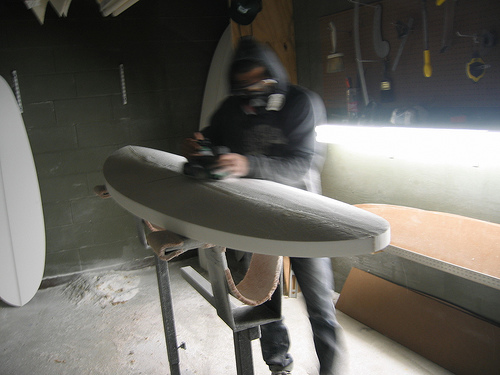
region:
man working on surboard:
[91, 47, 364, 373]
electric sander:
[185, 135, 228, 183]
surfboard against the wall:
[4, 75, 46, 318]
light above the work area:
[319, 118, 499, 173]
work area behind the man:
[317, 201, 499, 346]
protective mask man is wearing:
[232, 79, 289, 123]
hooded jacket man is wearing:
[211, 48, 313, 185]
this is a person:
[172, 32, 367, 368]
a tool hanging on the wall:
[370, 27, 406, 107]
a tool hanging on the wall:
[328, 10, 374, 118]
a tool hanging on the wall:
[398, 5, 453, 110]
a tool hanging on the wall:
[456, 11, 496, 101]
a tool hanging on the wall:
[102, 30, 147, 125]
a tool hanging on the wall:
[5, 61, 35, 127]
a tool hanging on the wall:
[312, 10, 353, 106]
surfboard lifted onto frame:
[103, 144, 391, 368]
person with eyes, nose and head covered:
[220, 30, 295, 118]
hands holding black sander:
[174, 132, 256, 185]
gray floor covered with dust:
[4, 249, 429, 369]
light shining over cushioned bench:
[320, 119, 495, 369]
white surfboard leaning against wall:
[3, 6, 51, 311]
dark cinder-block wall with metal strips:
[8, 7, 228, 290]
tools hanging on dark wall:
[305, 5, 495, 125]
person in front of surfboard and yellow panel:
[197, 4, 301, 180]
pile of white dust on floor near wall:
[55, 255, 146, 309]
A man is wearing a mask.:
[199, 33, 364, 370]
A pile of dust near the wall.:
[61, 258, 141, 325]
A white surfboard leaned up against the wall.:
[1, 79, 66, 310]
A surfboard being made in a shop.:
[102, 136, 386, 281]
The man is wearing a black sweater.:
[179, 37, 331, 192]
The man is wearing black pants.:
[236, 247, 343, 369]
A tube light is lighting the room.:
[316, 117, 498, 172]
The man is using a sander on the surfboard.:
[172, 128, 234, 189]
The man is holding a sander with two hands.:
[188, 42, 390, 372]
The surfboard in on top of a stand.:
[110, 225, 308, 371]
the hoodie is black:
[191, 38, 331, 195]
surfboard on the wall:
[0, 79, 52, 317]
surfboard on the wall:
[3, 68, 96, 334]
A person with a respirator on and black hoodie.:
[187, 38, 348, 373]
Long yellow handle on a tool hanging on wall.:
[420, 48, 430, 80]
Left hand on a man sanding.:
[205, 153, 247, 180]